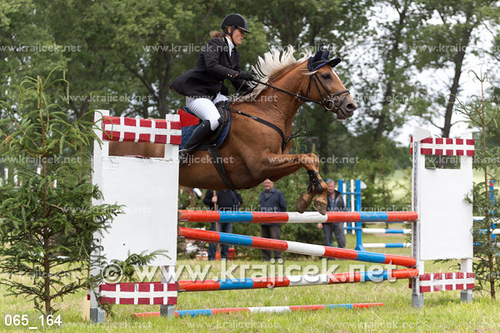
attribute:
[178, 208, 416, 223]
bar — blue, white, red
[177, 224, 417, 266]
bar — blue, white, red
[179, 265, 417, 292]
bar — blue, white, red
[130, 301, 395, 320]
bar — blue, white, red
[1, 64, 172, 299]
leaves — green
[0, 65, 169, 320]
tree — thin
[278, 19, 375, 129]
head — brown 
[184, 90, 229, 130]
pants — white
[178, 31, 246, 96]
jacket — black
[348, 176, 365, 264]
post — painted, royal blue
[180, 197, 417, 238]
post — painted, royal blue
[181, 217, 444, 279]
post — painted, royal blue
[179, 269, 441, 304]
post — painted, royal blue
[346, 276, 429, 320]
green grass — yellow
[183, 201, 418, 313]
piping — white, blue, red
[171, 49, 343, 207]
horse — brown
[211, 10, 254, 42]
hat — black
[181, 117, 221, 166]
boots — black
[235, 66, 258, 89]
gloves — black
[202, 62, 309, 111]
mane — blonde 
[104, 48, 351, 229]
horse — brown